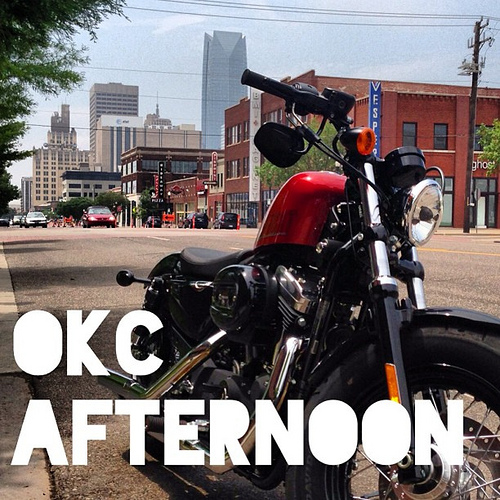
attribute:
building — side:
[200, 27, 252, 162]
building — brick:
[224, 71, 497, 231]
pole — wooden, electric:
[449, 19, 488, 231]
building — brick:
[183, 82, 458, 147]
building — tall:
[201, 30, 248, 150]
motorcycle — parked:
[95, 65, 498, 497]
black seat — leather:
[178, 241, 258, 279]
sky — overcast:
[1, 0, 498, 202]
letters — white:
[10, 308, 465, 467]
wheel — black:
[297, 319, 489, 498]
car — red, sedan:
[78, 201, 121, 230]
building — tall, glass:
[193, 27, 273, 179]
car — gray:
[19, 206, 54, 229]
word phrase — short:
[13, 282, 465, 488]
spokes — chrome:
[345, 391, 484, 492]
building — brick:
[119, 146, 221, 225]